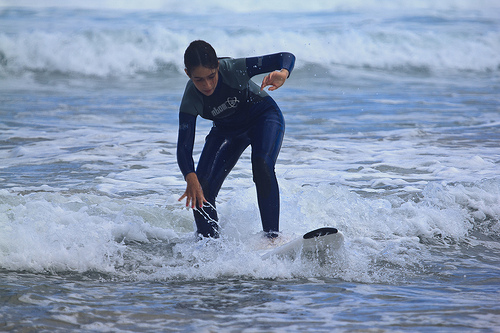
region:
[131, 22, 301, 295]
the woman's wet suit is blue.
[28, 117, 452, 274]
the waves are white.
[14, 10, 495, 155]
the water is blue.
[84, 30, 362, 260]
the surfer is female.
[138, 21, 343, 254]
the surf board is riding on the waves.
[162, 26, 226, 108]
the woman's hair is dark.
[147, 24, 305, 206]
the woman has two arms.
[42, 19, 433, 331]
the woman is in the water.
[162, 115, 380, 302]
the surf board is white.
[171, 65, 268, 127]
the logo is white.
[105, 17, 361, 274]
A woman surfing in water.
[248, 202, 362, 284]
A surfboard for the woman.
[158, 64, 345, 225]
A wetsuit for the woman surfing.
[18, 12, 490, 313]
A large body of water.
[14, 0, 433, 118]
Waves in the background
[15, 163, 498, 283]
Small waves for the woman to surf on.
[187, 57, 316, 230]
A blue and gray wetsuit.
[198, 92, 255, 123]
The brand of the wetsuit.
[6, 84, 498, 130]
Blue waters to surf in.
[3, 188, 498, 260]
White froth from the waves crashing.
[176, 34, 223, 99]
the head of a woman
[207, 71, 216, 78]
the eye of a woman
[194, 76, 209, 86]
the eye of a woman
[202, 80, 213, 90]
the nose of a woman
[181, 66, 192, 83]
the ear of a woman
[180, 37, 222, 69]
the hair of a woman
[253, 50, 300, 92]
the hand of a woman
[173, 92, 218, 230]
the hand of a woman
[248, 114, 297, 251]
the leg of a woman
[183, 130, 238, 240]
the leg of a woman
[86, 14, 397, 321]
a woman on a surfboard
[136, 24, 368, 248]
a woman bent forward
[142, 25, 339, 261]
a person wearing a wetsuit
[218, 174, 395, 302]
a surfboard in the water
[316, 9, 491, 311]
waves coming towards the shore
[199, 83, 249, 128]
a white logo on a wetsuit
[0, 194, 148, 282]
foamy salt water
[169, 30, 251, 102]
a woman with dark hair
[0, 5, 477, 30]
blue and white water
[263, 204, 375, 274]
a white surfboard with a black tip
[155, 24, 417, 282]
Woman on surfboard in water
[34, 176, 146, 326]
Frothy white sea foam waves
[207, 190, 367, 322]
White surfboard in water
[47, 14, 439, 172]
Big white wave in background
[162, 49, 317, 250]
scuba outfit on woman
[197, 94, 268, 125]
Advertising symbol on scuba outfit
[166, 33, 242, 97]
Dark brown thick hair on woman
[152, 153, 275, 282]
Right hand dripping water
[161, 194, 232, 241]
Bright orange red nail polish on woman's hand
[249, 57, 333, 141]
Left palm of woman's hand